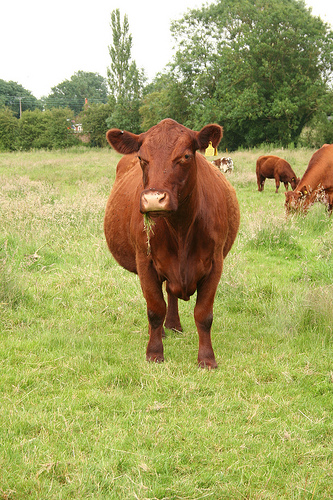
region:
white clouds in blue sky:
[23, 13, 48, 55]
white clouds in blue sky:
[10, 38, 41, 70]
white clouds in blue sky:
[28, 36, 54, 63]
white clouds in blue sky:
[44, 11, 100, 56]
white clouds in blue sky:
[132, 0, 168, 59]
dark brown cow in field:
[90, 119, 239, 370]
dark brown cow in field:
[240, 149, 292, 187]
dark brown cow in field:
[278, 140, 322, 224]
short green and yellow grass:
[34, 381, 97, 415]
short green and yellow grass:
[193, 412, 287, 468]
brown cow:
[97, 117, 244, 376]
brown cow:
[251, 143, 300, 187]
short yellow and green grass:
[24, 360, 65, 384]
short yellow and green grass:
[156, 385, 201, 431]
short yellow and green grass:
[216, 411, 248, 449]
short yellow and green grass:
[53, 385, 98, 436]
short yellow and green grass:
[57, 346, 109, 392]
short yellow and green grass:
[44, 227, 68, 273]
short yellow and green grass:
[25, 174, 55, 230]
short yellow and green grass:
[45, 170, 77, 199]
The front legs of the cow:
[139, 257, 217, 367]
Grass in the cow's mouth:
[142, 212, 155, 251]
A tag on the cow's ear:
[204, 144, 214, 156]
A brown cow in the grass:
[105, 122, 240, 369]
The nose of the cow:
[139, 192, 166, 203]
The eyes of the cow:
[138, 154, 190, 161]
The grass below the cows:
[0, 148, 330, 499]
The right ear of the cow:
[106, 129, 139, 153]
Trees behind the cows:
[0, 1, 332, 153]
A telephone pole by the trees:
[12, 95, 24, 118]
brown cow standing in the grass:
[97, 119, 227, 369]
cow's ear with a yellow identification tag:
[195, 124, 222, 157]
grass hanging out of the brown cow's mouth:
[139, 193, 168, 257]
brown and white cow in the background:
[211, 157, 234, 173]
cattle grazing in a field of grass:
[104, 119, 331, 373]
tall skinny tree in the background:
[107, 5, 144, 122]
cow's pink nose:
[141, 190, 169, 209]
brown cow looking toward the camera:
[107, 122, 222, 369]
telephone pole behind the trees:
[15, 95, 24, 118]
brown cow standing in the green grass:
[103, 119, 235, 373]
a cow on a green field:
[94, 107, 246, 378]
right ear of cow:
[193, 117, 224, 156]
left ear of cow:
[101, 120, 144, 159]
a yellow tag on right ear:
[190, 123, 229, 162]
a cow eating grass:
[246, 137, 331, 232]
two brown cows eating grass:
[247, 132, 331, 233]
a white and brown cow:
[212, 150, 243, 176]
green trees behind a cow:
[4, 4, 331, 156]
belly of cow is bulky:
[95, 187, 249, 279]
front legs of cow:
[142, 273, 220, 376]